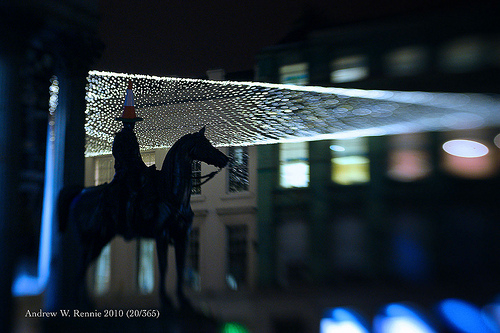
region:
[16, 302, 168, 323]
photo tag on the picture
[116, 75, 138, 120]
traffic cone on the man's head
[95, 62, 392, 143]
lights going across the street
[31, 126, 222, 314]
horse at the corner of the street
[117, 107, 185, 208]
man on a horse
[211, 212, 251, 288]
window in a building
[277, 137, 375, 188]
lights on in the building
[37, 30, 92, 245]
column on the building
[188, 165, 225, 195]
reins on the horse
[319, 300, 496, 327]
blue lights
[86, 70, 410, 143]
curtain of white lights at nighttime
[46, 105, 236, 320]
one dark statue silhouette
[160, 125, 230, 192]
shadowed horse head statue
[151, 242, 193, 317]
two shadowed horse statue legs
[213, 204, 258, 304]
one rectangular building window at night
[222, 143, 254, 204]
one rectangular reflective window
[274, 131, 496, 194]
several building windows at night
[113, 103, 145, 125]
shadowed hat of horse rider statue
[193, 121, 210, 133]
pointy horse statue ear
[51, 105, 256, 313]
one large statue in front of building at night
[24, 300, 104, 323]
Person who took the photo.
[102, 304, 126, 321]
Year the photo was taken.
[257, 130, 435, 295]
Building with many windows.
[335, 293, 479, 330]
Blurred blue lights in the photo.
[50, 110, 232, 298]
Horse and rider statue.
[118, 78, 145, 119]
Small figure standing on the rider.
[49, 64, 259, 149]
Lights above the statue.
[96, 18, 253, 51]
Very dark night sky.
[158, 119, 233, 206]
The horse is wearing a bridle.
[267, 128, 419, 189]
Lights turned on because of the darkness.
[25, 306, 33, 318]
white print style letter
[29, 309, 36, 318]
white print style letter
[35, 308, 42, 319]
white print style letter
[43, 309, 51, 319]
white print style letter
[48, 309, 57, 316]
white print style letter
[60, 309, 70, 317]
white print style letter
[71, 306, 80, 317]
white print style letter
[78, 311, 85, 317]
white print style letter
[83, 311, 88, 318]
white print style letter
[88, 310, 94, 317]
white print style letter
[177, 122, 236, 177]
head of a horse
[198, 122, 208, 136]
ear of a horse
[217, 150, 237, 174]
mouth of a horse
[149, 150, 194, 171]
neck of a horse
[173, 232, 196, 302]
leg of a horse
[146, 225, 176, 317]
leg of a horse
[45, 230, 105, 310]
legs of a horse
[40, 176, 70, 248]
tail of a horse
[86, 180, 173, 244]
body of a horse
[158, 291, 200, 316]
feet of a horse